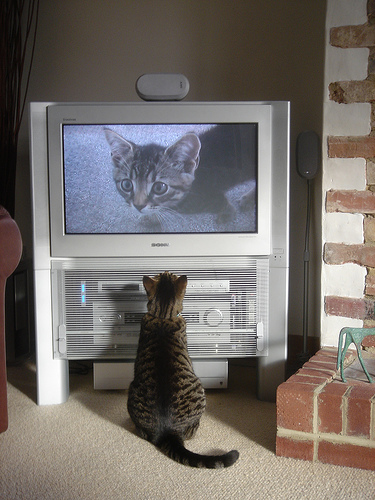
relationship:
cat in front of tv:
[127, 271, 238, 468] [47, 105, 274, 256]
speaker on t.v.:
[134, 72, 189, 99] [47, 103, 273, 256]